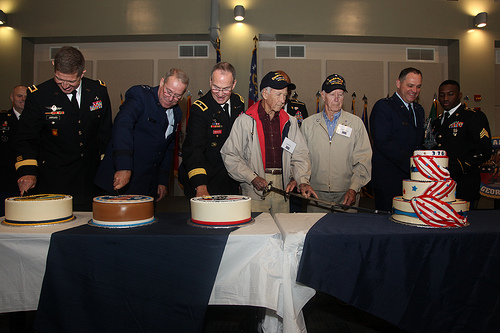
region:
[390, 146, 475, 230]
Cake on the table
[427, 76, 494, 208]
Man wearing a uniform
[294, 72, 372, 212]
Man wearing a blue shirt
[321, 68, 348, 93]
Hat on the man's head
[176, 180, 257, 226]
Cake on the table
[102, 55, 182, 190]
Man wearing a blue jacket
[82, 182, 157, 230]
Cake on the table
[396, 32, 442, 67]
Vent on the wall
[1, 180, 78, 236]
Cake on the table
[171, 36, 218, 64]
Vent on the wall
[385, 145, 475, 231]
a red, white and blue cake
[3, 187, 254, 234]
3 cakes in a row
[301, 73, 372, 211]
a man wearing a beige jacket and ball cap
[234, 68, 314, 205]
a man wearing a beige jacket with a red liner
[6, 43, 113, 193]
a soldier in uniform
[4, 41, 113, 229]
a soldier in uniform cutting a cake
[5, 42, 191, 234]
2 men cutting cakes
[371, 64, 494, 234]
2 men standing in front of a fancy cake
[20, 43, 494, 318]
7 men in front of a table full of cakes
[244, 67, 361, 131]
2 men wearing ball caps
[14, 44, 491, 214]
the men in front of the tables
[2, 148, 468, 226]
the cakes on the tables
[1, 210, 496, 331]
the tables in front of the men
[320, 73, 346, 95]
the hat on the man's head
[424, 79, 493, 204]
the man wearing a military uniform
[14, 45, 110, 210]
the man wearing a military uniform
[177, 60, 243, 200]
the man wearing a military uniform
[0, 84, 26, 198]
the man in the background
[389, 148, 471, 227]
the red, white and blue cake on the table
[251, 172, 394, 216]
the long sword in the man's hand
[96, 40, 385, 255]
men standing behind table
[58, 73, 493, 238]
men standing behind cakes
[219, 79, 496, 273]
a man cutting a cake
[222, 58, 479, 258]
a man cutting a cake with sword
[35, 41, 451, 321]
men that are uniform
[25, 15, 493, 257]
men in miltary uniform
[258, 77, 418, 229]
men wearing hats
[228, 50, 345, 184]
men wearing jackets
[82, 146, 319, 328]
blue and white table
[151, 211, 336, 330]
blue and white table cloth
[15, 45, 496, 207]
men standing at table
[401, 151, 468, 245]
three layer cake on table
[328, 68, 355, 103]
man has black cap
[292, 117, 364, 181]
man has grey coat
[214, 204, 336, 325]
white cloth on table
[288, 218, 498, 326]
blue cover on table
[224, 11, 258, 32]
small lights on ceiling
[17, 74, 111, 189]
black and yellow uniform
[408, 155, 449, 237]
red white and blue cake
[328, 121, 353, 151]
man has white name tag